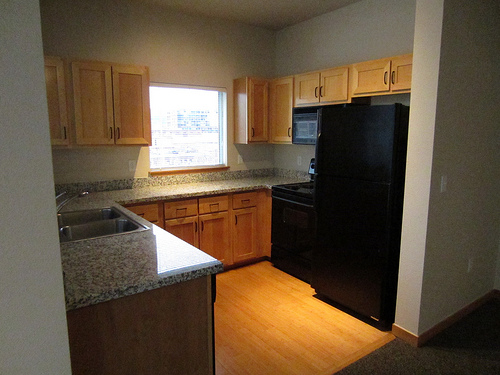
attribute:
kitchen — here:
[108, 131, 319, 294]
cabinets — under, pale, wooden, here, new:
[187, 198, 268, 250]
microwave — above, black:
[285, 102, 328, 142]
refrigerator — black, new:
[321, 108, 398, 286]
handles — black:
[172, 200, 218, 235]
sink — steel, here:
[68, 207, 145, 265]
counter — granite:
[86, 197, 171, 311]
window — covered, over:
[147, 88, 198, 154]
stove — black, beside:
[288, 177, 313, 196]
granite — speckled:
[135, 194, 169, 200]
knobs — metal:
[373, 63, 412, 93]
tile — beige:
[222, 270, 316, 363]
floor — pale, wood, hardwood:
[253, 286, 341, 369]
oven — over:
[287, 112, 322, 153]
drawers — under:
[164, 195, 237, 229]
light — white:
[434, 166, 478, 227]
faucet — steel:
[60, 184, 87, 211]